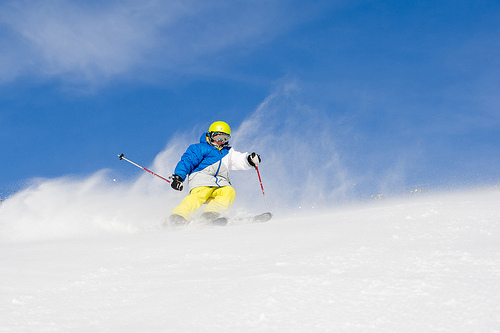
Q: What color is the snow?
A: White.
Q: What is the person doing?
A: Skiing.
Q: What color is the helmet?
A: Yellow.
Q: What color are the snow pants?
A: Yellow.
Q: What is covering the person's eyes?
A: Goggles.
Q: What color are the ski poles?
A: Red and white.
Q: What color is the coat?
A: Blue, grey and white.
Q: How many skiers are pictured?
A: One.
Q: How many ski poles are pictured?
A: Two.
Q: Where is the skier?
A: On a hill.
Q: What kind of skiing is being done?
A: Downhill skiing.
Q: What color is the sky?
A: Blue.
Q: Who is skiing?
A: A person.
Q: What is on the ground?
A: Snow.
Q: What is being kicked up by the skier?
A: Snow.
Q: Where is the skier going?
A: Down the hill.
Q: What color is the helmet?
A: Yellow.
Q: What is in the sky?
A: Cloud.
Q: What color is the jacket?
A: Blue and white.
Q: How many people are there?
A: One.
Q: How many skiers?
A: 1.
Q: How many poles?
A: 2.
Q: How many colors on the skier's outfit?
A: 3.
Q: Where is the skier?
A: Mountains.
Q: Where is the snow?
A: On ground.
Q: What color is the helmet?
A: Yellow.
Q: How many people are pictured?
A: One.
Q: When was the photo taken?
A: In a snow valley.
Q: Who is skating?
A: A man.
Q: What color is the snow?
A: White.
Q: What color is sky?
A: Blue.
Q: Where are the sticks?
A: ON THE MAN'S HAND.